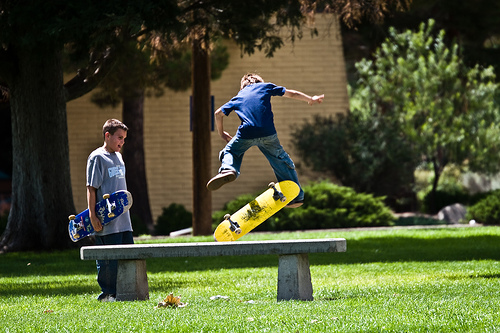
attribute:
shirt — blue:
[216, 82, 290, 140]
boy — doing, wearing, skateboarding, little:
[199, 68, 346, 210]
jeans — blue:
[219, 133, 313, 199]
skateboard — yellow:
[209, 176, 306, 244]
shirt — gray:
[75, 145, 146, 232]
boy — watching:
[76, 117, 153, 304]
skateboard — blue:
[63, 186, 135, 242]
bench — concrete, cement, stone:
[75, 235, 358, 302]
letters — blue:
[104, 163, 130, 178]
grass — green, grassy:
[1, 227, 500, 332]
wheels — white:
[264, 177, 297, 209]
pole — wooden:
[190, 5, 215, 234]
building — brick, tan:
[61, 4, 359, 213]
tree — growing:
[3, 4, 178, 240]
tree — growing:
[371, 23, 495, 210]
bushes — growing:
[227, 182, 386, 229]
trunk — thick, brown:
[10, 44, 76, 245]